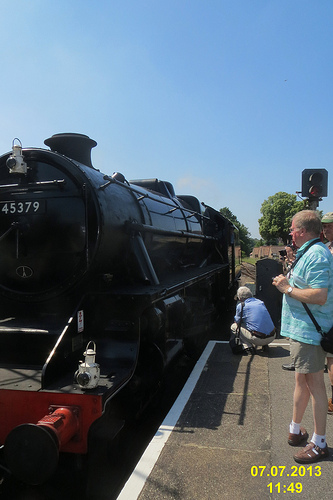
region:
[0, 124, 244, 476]
an old locomotive standing alone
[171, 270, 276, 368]
a man examines the engine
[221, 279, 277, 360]
a man in a blue shirt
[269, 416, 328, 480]
a guy wearing sandals and socks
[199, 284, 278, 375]
a gray man sight seeing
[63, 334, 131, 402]
a white lamp on the engine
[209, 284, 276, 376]
a man with a satchel on his shoulder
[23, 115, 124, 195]
the stack of a steam engine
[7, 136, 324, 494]
a locomotive by a platform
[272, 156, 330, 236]
a signal light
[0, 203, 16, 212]
First two numbers in front of train.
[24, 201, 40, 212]
Last two numbers in front of train.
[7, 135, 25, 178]
White light structure in front of train.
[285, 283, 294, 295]
Watch on man's wrist in brown sandals.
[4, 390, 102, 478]
Red paint on train.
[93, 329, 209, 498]
White boundary line where people are standing.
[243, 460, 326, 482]
Date stamped on photo.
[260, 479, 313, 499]
Time stamped on photo.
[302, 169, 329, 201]
Traffic light above people looking at the train.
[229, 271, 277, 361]
Man crouching down near white boundary line in blue shirt.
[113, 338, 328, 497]
concrete train station platform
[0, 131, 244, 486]
black and red train leaving station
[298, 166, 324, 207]
train track traffic light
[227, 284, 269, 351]
older man wearing a shoulder bag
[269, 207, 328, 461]
man wearing glasses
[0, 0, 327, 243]
clear blue sky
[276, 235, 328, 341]
teal striped mens polo shirt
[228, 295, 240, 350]
black hand bag being carried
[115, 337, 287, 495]
white painted line on platform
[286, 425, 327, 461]
brown mens sandals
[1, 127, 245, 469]
the train is black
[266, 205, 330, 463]
the man is old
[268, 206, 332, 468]
the man is wearing a watch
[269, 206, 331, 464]
the man is wearing sandles and socks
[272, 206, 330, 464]
the man's shirt is blue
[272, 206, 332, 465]
the man is carrying a bag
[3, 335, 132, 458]
the bumper of the train is red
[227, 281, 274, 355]
the man is kneeling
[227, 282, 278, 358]
the man's shirt is blue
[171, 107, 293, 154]
clear blue skies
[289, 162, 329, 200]
black signal lights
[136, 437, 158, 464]
white lines on pavement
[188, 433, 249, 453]
jagged line on pavement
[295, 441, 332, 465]
man's brown shoes with buckle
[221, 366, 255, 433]
shadow of train on asphalt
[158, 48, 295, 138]
clear blue skies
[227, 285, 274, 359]
person stooping on pavement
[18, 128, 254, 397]
large black shiny train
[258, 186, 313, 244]
large clump of green trees